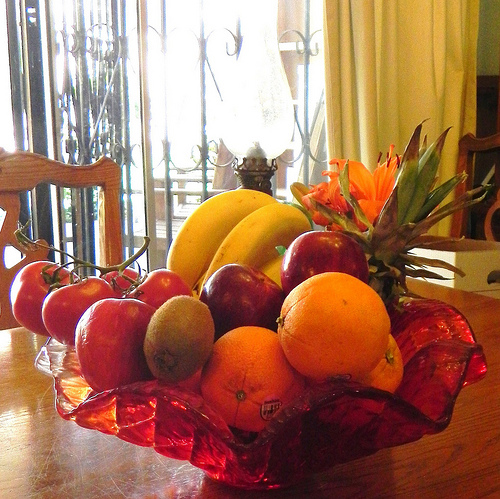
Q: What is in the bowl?
A: Fruit.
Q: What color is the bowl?
A: Red.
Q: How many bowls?
A: One.